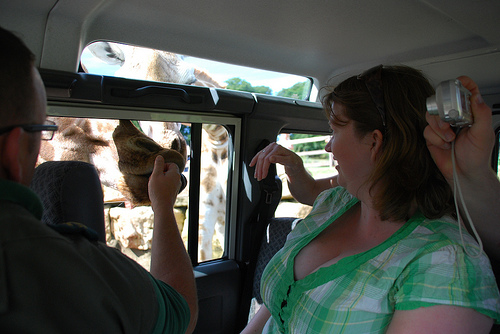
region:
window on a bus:
[195, 113, 243, 274]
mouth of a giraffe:
[121, 144, 188, 206]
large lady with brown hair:
[230, 52, 491, 333]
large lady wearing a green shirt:
[227, 59, 493, 333]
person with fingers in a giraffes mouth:
[0, 18, 201, 333]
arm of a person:
[129, 153, 206, 333]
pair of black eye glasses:
[0, 116, 65, 152]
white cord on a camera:
[437, 132, 491, 262]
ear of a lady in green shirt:
[362, 123, 386, 167]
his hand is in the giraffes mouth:
[143, 152, 185, 195]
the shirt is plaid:
[438, 257, 470, 282]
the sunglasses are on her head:
[353, 62, 391, 118]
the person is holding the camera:
[426, 77, 483, 128]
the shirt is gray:
[79, 257, 102, 285]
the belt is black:
[252, 211, 268, 232]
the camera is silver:
[432, 85, 452, 111]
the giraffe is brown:
[111, 142, 137, 169]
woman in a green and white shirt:
[238, 62, 490, 333]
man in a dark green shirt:
[0, 28, 201, 333]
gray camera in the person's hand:
[424, 79, 474, 127]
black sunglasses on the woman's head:
[356, 63, 393, 133]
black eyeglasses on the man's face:
[2, 121, 56, 143]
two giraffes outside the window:
[37, 46, 241, 264]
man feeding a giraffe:
[0, 28, 199, 330]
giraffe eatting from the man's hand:
[36, 111, 192, 201]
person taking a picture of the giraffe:
[420, 70, 498, 236]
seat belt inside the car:
[232, 162, 279, 332]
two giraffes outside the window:
[44, 44, 231, 261]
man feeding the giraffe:
[0, 31, 199, 331]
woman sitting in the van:
[238, 64, 497, 333]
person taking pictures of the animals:
[422, 76, 499, 251]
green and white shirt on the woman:
[257, 186, 498, 333]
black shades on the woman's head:
[353, 64, 388, 129]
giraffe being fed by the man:
[38, 89, 186, 203]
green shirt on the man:
[0, 177, 192, 329]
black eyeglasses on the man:
[0, 120, 58, 140]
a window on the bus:
[66, 115, 226, 252]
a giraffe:
[59, 105, 184, 194]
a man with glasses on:
[1, 27, 151, 324]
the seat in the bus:
[36, 160, 103, 228]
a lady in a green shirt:
[275, 78, 490, 328]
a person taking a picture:
[416, 75, 493, 170]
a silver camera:
[423, 83, 477, 128]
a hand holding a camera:
[414, 60, 498, 171]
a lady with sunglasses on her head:
[314, 52, 468, 250]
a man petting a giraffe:
[0, 33, 223, 330]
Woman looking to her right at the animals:
[255, 56, 465, 330]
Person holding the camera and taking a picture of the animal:
[416, 72, 490, 127]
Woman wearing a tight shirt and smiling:
[210, 68, 472, 325]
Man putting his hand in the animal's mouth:
[6, 31, 277, 329]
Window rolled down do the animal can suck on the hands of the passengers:
[36, 74, 270, 286]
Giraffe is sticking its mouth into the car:
[51, 50, 227, 236]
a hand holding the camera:
[420, 67, 496, 178]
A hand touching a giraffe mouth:
[137, 141, 190, 208]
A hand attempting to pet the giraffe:
[244, 139, 306, 186]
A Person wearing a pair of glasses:
[2, 31, 63, 208]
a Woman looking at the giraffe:
[265, 57, 449, 328]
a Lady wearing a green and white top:
[252, 61, 490, 331]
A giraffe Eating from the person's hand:
[104, 125, 186, 206]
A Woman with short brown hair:
[314, 56, 443, 229]